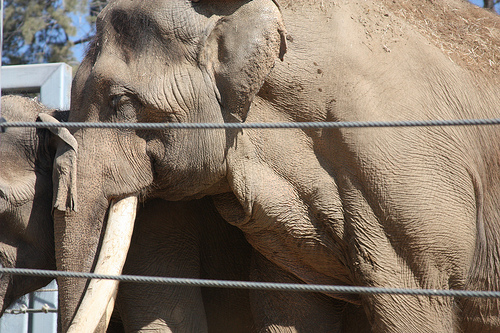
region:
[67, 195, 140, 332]
an elephants white tusk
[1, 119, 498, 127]
a wire fence in the elephants pen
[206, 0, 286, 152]
an elephants injured ear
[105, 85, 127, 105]
an elephants sad eyes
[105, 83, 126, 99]
the elephants grey eyebrows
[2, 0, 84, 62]
tall trees outside the elephant pen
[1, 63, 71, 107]
a metal gate door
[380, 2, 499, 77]
dirt on the elephants back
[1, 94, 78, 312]
a smaller elephant next to the sad elephant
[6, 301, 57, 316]
barbed wire fence on the opposite side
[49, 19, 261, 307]
elephant has brown face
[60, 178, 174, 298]
elephant has white tusk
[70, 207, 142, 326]
elephant has long tusk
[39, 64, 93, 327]
elephant has brown trunk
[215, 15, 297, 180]
elephant has brown ears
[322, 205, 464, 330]
elephant has brown legs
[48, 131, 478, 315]
wire fence in front of elephant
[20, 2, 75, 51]
tall trees in distance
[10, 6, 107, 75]
blue sky behind trees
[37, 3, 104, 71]
no clouds in sky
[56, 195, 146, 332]
TUSK OF LARGE ELEPHANT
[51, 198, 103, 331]
TRUNK OF LARGE ELEPHANT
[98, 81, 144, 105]
EYE OF LARGE ELEPHANT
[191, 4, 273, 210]
EAR OF LARGE ELEPHANT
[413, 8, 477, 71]
DIRT ON BACK OF ELEPHANT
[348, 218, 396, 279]
WRINKLED SKIN OF LARGE ELEPHANT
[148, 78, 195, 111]
WRINKLED SKIN OF LARGE ELEPHANT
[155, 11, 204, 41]
WRINKLED SKIN OF LARGE ELEPHANT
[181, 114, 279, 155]
RETAINING WIRE OF ELEPHANT STOCKADE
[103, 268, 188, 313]
RETAINING WIRE OF ELEPHANT STOCKADE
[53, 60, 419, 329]
elephants in a field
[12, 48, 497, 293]
a field with elephants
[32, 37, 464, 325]
elephants in an area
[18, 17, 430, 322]
an area with elephants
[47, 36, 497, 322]
elephants in a fenced in area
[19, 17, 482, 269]
elephants with closed eyes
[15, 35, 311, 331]
elephant with long tusk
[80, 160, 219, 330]
elephant with long white tusk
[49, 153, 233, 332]
elephant with white tusk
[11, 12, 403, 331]
an elephant that is sleeping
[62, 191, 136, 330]
The tusk is white.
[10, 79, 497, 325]
The elephant is behind wire.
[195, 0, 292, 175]
His ear are large.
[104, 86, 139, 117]
His eyes are closed.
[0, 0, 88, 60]
The tree is green.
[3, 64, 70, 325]
This gate is white.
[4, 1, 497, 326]
There are two elephants here.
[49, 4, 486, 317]
The elephant is grey.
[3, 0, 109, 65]
It is day time out.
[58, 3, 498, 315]
The elephant is standing.